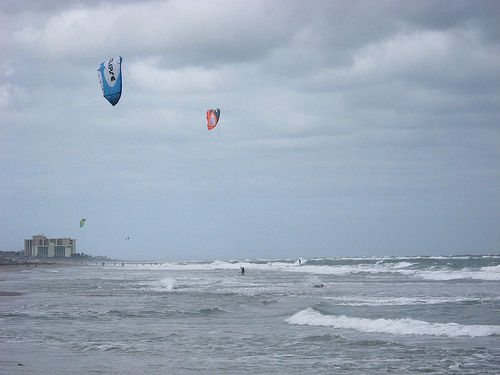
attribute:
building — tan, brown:
[16, 234, 86, 261]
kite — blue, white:
[77, 50, 138, 120]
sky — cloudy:
[1, 1, 498, 260]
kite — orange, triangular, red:
[197, 104, 224, 132]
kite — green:
[77, 217, 87, 228]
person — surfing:
[236, 266, 251, 280]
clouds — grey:
[2, 1, 499, 184]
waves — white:
[291, 307, 500, 334]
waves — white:
[130, 257, 500, 283]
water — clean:
[1, 255, 498, 374]